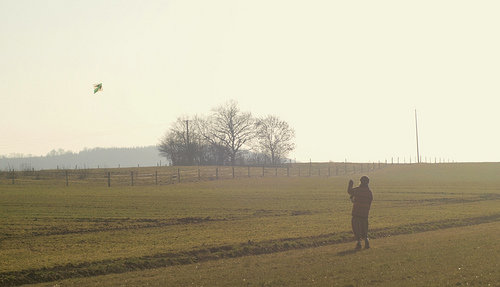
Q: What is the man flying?
A: A kite.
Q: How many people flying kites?
A: One.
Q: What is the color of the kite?
A: Green and yellow.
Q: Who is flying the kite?
A: A man.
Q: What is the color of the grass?
A: Green.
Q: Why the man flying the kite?
A: For entertainment.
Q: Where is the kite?
A: Floating.